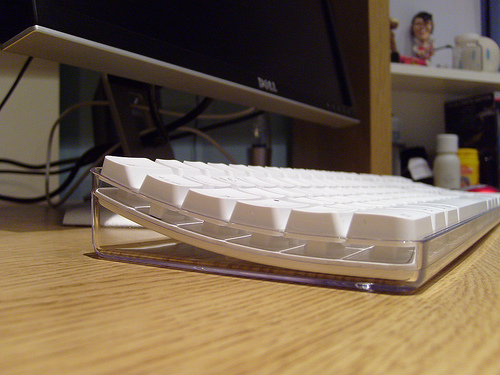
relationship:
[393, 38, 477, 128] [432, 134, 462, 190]
shelf with containers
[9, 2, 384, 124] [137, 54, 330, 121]
computer with frame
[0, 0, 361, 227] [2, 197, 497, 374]
computer on table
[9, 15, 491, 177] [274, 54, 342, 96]
monitor with screen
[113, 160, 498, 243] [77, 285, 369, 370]
board on desk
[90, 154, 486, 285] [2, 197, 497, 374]
keyboard on table